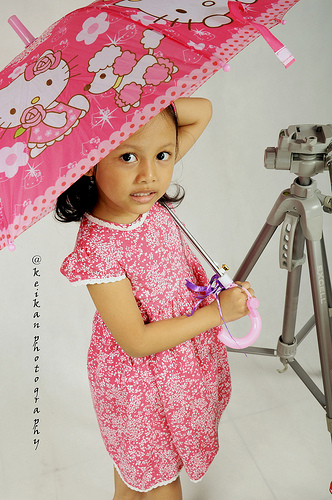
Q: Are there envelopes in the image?
A: No, there are no envelopes.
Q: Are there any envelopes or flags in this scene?
A: No, there are no envelopes or flags.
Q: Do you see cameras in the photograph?
A: Yes, there is a camera.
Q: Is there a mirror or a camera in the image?
A: Yes, there is a camera.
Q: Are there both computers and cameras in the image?
A: No, there is a camera but no computers.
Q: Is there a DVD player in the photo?
A: No, there are no DVD players.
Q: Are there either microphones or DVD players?
A: No, there are no DVD players or microphones.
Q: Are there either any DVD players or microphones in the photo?
A: No, there are no DVD players or microphones.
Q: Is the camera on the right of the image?
A: Yes, the camera is on the right of the image.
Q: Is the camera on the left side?
A: No, the camera is on the right of the image.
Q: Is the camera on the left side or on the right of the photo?
A: The camera is on the right of the image.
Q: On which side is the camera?
A: The camera is on the right of the image.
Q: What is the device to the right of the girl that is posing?
A: The device is a camera.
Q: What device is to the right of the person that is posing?
A: The device is a camera.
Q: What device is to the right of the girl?
A: The device is a camera.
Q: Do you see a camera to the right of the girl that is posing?
A: Yes, there is a camera to the right of the girl.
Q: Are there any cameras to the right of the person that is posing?
A: Yes, there is a camera to the right of the girl.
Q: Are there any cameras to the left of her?
A: No, the camera is to the right of the girl.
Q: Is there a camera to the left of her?
A: No, the camera is to the right of the girl.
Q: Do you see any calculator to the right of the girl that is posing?
A: No, there is a camera to the right of the girl.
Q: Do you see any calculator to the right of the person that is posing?
A: No, there is a camera to the right of the girl.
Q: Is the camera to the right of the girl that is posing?
A: Yes, the camera is to the right of the girl.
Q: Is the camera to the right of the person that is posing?
A: Yes, the camera is to the right of the girl.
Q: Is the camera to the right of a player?
A: No, the camera is to the right of the girl.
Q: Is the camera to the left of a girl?
A: No, the camera is to the right of a girl.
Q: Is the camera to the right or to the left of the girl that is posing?
A: The camera is to the right of the girl.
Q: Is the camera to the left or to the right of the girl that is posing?
A: The camera is to the right of the girl.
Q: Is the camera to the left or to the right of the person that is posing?
A: The camera is to the right of the girl.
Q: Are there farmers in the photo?
A: No, there are no farmers.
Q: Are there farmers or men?
A: No, there are no farmers or men.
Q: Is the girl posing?
A: Yes, the girl is posing.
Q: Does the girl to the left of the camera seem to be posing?
A: Yes, the girl is posing.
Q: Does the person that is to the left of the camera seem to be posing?
A: Yes, the girl is posing.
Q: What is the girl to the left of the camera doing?
A: The girl is posing.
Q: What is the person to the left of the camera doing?
A: The girl is posing.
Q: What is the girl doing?
A: The girl is posing.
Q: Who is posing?
A: The girl is posing.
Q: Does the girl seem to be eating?
A: No, the girl is posing.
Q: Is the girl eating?
A: No, the girl is posing.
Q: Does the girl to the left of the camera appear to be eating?
A: No, the girl is posing.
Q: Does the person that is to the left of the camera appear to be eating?
A: No, the girl is posing.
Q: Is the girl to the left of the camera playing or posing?
A: The girl is posing.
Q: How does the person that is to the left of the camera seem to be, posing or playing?
A: The girl is posing.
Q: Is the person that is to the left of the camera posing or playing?
A: The girl is posing.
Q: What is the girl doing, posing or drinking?
A: The girl is posing.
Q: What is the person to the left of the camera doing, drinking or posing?
A: The girl is posing.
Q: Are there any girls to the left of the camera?
A: Yes, there is a girl to the left of the camera.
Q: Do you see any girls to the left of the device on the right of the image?
A: Yes, there is a girl to the left of the camera.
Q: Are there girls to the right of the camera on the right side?
A: No, the girl is to the left of the camera.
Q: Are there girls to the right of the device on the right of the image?
A: No, the girl is to the left of the camera.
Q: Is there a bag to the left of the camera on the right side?
A: No, there is a girl to the left of the camera.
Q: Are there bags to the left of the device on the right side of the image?
A: No, there is a girl to the left of the camera.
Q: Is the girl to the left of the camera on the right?
A: Yes, the girl is to the left of the camera.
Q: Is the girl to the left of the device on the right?
A: Yes, the girl is to the left of the camera.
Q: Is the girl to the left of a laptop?
A: No, the girl is to the left of the camera.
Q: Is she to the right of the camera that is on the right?
A: No, the girl is to the left of the camera.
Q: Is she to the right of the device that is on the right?
A: No, the girl is to the left of the camera.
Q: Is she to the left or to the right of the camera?
A: The girl is to the left of the camera.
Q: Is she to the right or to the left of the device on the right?
A: The girl is to the left of the camera.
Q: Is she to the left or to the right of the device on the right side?
A: The girl is to the left of the camera.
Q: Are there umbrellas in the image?
A: Yes, there is an umbrella.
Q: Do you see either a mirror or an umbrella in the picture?
A: Yes, there is an umbrella.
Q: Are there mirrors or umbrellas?
A: Yes, there is an umbrella.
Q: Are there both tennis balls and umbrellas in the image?
A: No, there is an umbrella but no tennis balls.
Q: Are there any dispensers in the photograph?
A: No, there are no dispensers.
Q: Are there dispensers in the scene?
A: No, there are no dispensers.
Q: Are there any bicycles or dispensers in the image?
A: No, there are no dispensers or bicycles.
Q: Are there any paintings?
A: No, there are no paintings.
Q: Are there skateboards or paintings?
A: No, there are no paintings or skateboards.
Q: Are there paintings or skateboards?
A: No, there are no paintings or skateboards.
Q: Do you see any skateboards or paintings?
A: No, there are no paintings or skateboards.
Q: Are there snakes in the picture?
A: No, there are no snakes.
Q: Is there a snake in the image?
A: No, there are no snakes.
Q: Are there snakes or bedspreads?
A: No, there are no snakes or bedspreads.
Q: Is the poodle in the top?
A: Yes, the poodle is in the top of the image.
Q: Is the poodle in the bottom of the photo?
A: No, the poodle is in the top of the image.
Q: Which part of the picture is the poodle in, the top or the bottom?
A: The poodle is in the top of the image.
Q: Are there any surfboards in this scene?
A: No, there are no surfboards.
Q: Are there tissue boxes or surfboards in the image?
A: No, there are no surfboards or tissue boxes.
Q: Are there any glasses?
A: No, there are no glasses.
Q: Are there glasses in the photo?
A: No, there are no glasses.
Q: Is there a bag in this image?
A: No, there are no bags.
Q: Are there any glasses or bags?
A: No, there are no bags or glasses.